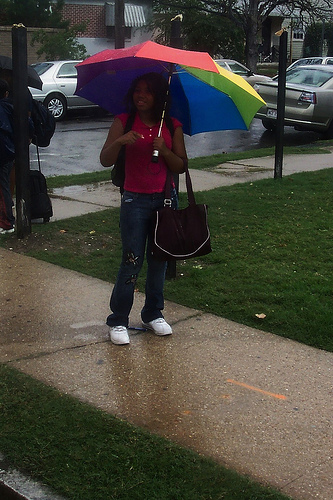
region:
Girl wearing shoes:
[106, 314, 172, 344]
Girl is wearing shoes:
[104, 311, 176, 350]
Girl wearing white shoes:
[105, 306, 176, 349]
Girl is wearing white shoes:
[103, 311, 176, 351]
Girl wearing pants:
[107, 183, 180, 330]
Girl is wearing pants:
[102, 186, 178, 327]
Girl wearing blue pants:
[106, 174, 179, 329]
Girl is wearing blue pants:
[105, 182, 182, 330]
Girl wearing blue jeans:
[106, 184, 178, 330]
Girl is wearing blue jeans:
[107, 182, 181, 329]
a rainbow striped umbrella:
[73, 39, 266, 135]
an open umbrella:
[73, 40, 266, 137]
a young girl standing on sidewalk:
[97, 75, 213, 347]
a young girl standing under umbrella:
[72, 39, 266, 345]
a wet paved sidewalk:
[0, 245, 330, 499]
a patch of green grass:
[1, 363, 285, 498]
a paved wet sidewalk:
[0, 148, 332, 230]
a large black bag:
[149, 158, 213, 260]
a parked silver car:
[251, 64, 331, 138]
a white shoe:
[106, 324, 132, 346]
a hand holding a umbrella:
[151, 136, 184, 169]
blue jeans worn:
[118, 197, 139, 319]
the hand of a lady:
[102, 117, 142, 162]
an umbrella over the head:
[98, 37, 252, 99]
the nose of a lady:
[138, 93, 147, 98]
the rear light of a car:
[300, 90, 317, 105]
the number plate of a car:
[264, 108, 280, 117]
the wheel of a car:
[45, 96, 64, 116]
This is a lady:
[93, 50, 207, 347]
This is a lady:
[105, 74, 199, 358]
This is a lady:
[72, 66, 228, 379]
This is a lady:
[80, 55, 214, 345]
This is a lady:
[74, 58, 223, 360]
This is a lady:
[94, 71, 188, 360]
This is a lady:
[73, 58, 219, 368]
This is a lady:
[82, 61, 228, 383]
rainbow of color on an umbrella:
[72, 39, 266, 138]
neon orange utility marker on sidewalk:
[220, 368, 289, 403]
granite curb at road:
[0, 458, 69, 499]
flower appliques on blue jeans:
[121, 247, 142, 291]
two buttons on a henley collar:
[146, 124, 155, 142]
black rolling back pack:
[26, 127, 54, 227]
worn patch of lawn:
[5, 196, 120, 282]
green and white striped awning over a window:
[104, 0, 147, 30]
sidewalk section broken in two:
[202, 156, 280, 185]